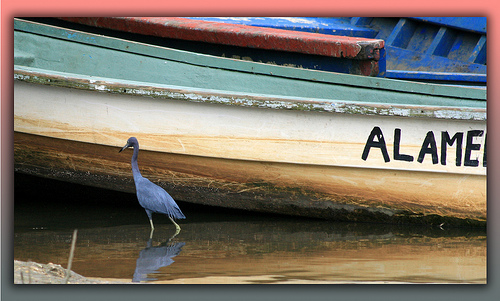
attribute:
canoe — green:
[10, 17, 485, 222]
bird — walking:
[120, 137, 186, 243]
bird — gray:
[114, 134, 190, 250]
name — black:
[309, 98, 489, 194]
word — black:
[351, 115, 491, 176]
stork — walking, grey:
[118, 136, 186, 246]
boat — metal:
[7, 15, 484, 224]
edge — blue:
[344, 14, 488, 84]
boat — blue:
[356, 14, 496, 103]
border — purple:
[224, 0, 497, 14]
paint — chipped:
[97, 78, 298, 123]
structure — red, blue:
[17, 20, 486, 94]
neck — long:
[126, 145, 142, 172]